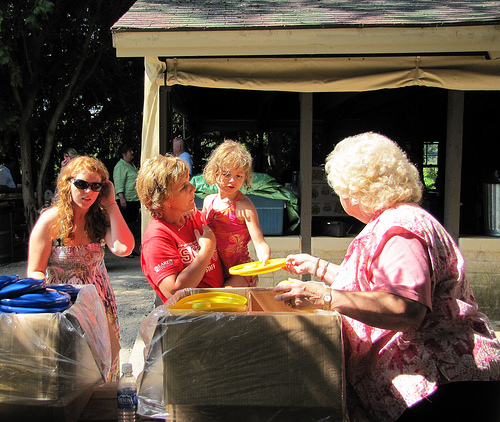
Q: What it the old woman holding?
A: A plate.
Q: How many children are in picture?
A: 1.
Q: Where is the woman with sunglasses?
A: Behind the woman with the child.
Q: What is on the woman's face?
A: Sunglasses.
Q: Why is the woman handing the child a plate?
A: So she can get food.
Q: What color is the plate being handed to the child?
A: Yellow.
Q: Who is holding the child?
A: A woman.